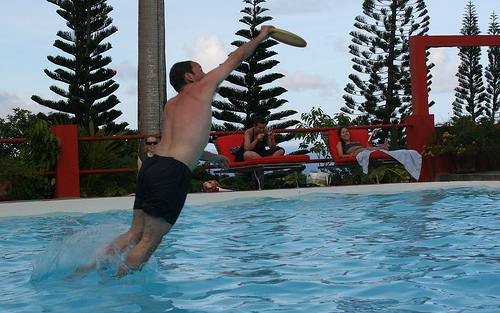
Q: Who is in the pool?
A: A man.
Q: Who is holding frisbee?
A: A man.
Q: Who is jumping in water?
A: A man.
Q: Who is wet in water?
A: A man.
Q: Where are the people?
A: Beside pool.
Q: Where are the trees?
A: By pool.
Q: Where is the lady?
A: In chair.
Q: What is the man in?
A: A water.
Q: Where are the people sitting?
A: Alongside the pool.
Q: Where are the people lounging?
A: On chaise lounges.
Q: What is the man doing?
A: Catching a frisbee.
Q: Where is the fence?
A: Around the pool.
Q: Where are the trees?
A: Outside of the pool area.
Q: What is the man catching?
A: A frisbee.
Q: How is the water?
A: Calm and blue.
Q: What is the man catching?
A: Frisbee.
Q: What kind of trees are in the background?
A: Pine trees.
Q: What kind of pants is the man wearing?
A: Shorts.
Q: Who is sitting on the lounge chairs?
A: Two women.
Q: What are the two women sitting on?
A: Lounge chairs.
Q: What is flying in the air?
A: Frisbee.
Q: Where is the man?
A: Pool.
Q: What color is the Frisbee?
A: Tan.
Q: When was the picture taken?
A: Daytime.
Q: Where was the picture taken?
A: At a pool.